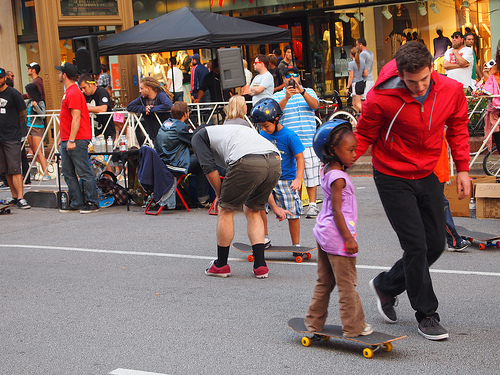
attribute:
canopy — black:
[98, 7, 291, 58]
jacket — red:
[350, 58, 476, 176]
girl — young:
[308, 124, 377, 336]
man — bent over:
[191, 120, 278, 278]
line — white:
[5, 236, 499, 287]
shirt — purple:
[314, 168, 363, 256]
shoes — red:
[207, 258, 272, 281]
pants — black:
[369, 169, 447, 313]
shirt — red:
[55, 87, 94, 143]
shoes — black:
[366, 273, 449, 343]